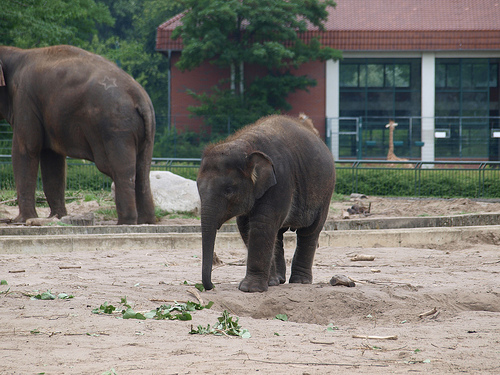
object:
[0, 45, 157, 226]
elephant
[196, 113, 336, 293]
elephant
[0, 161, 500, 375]
zoo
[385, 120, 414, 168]
giraffe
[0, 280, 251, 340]
leaves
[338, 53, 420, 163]
windows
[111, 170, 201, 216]
boulder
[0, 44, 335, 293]
elephants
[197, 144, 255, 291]
head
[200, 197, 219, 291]
trunk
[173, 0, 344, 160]
tree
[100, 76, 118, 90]
star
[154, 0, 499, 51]
roof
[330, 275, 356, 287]
rock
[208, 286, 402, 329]
hole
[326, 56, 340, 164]
column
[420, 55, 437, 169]
column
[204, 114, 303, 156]
hair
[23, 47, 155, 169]
back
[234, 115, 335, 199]
back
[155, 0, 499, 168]
bar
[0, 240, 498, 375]
ground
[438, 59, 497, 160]
window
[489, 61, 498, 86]
part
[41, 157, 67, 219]
leg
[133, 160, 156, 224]
leg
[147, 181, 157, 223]
edge